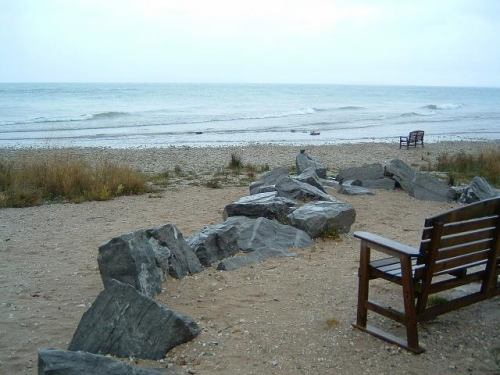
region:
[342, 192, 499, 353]
Wooden bench facing the ocean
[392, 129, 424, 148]
Wooden bench facing the ocean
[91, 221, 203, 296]
Large gray rock next to rock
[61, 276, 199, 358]
Large gray rock next to rock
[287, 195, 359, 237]
Large gray rock next to rock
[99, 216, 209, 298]
Large gray rock in front of wooden bench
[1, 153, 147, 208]
European beach grass piled together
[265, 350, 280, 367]
Tiny rock on sand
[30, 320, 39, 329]
Tiny rock on sand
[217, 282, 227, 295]
Tiny rock on sand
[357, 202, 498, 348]
bench behind the rocks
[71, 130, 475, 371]
rocks are large and grey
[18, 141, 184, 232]
sea grass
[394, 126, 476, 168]
bench by the water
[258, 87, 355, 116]
waves in the water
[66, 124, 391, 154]
shoreline along the beach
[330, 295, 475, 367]
rocks in the sand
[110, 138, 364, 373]
rocks are in a line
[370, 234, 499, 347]
bench is made of wood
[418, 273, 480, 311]
grass in the sand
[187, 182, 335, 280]
Grey rocks on the sand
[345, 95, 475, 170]
bench near beach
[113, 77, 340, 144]
blue ocean water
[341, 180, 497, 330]
bench on the sand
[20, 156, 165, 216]
brown colored grass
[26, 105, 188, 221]
grass near the beach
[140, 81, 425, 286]
rocks on the beach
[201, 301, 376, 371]
white rocks on the sand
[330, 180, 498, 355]
brown colored bench on sand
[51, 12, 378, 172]
clear skies near beach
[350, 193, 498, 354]
perfectly constructed heavy wood bench in the foreground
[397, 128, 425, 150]
small heavy duty wood bench in the background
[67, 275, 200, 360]
dark gray triangular rock with white speckled stripes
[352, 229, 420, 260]
arm rest from a wooden bench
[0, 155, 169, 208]
long grass and reeds growing by the ocean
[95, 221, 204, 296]
gray 3D slate rock with white non-symetric spots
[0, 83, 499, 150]
wide spanned ocean filled with water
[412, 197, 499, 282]
back of a bench made with slatted wood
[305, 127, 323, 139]
some type of floater in the water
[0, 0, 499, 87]
light bluish grayish white sky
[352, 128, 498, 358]
Two benches on a beach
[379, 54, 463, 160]
Bench overlooking the water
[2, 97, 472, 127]
Waves in the water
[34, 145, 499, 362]
Large gray rocks in the sand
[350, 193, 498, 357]
Brown wooden bench in the sand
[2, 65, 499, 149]
Calm blue ocean with small waves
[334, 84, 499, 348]
Brown benches overlooking the water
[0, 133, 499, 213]
Vegetation and rocks on the beach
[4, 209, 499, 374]
Sand with large and small rocks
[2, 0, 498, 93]
Blue sky without any clouds